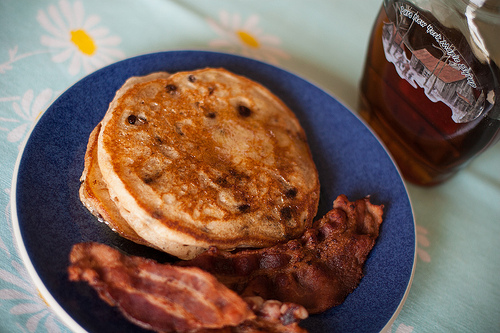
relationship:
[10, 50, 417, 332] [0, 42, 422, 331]
breakfast on plate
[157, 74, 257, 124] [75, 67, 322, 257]
blueberries on pancake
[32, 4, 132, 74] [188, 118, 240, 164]
daisy has yellow center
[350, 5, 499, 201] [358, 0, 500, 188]
bottle has maple syrup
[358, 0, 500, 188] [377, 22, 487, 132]
maple syrup from new york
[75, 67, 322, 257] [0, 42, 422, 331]
pancake on plate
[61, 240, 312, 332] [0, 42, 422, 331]
slice of bacon on plate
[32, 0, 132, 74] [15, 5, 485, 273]
daisy on tablecloth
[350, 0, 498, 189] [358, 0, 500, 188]
bottle of maple syrup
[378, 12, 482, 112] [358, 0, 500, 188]
illustration on maple syrup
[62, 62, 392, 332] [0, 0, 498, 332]
breakfast on blue plate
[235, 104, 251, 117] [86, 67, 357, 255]
chocolate chip on pancake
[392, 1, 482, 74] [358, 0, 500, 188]
words on maple syrup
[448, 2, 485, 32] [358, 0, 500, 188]
reflection on maple syrup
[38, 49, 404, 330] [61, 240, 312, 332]
blue plate with slice of bacon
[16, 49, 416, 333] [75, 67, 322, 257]
blue plate with pancake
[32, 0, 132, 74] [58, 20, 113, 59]
daisy with yellow center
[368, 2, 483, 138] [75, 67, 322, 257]
syrup on pancake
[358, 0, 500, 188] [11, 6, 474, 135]
maple syrup on table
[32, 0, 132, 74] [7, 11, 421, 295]
daisy on tablecloth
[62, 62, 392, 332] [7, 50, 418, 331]
breakfast on blue plate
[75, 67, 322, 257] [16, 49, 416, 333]
pancake on blue plate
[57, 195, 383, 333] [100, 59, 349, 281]
slices of bacon under pancakes